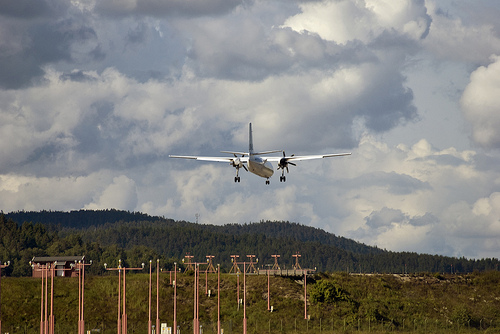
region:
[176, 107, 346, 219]
airplane landing in the mountains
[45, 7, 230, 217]
dark clouds in the background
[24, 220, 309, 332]
power lines in mountainous terrain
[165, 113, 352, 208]
airplane with landing gear down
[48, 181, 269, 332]
green mountains behind power lines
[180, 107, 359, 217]
white airplane with propellers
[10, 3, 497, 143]
dark and light clouds in the sky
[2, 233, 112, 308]
red building behind power lines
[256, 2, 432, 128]
sun hiding in clouds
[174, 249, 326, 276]
small bridge at top of hill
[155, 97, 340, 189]
a plane in the air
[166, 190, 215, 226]
A tower in the distance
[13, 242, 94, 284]
A building on a hill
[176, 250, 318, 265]
A line of red structures in the distance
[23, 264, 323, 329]
lines of lights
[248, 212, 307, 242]
A hill covered in trees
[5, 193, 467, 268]
A forest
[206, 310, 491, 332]
A fence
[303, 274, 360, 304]
A bush on a hill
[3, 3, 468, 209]
A very cloudy sky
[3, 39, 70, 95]
dark clouds rolling in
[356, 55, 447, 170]
fluffy white clouds in the sky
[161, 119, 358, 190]
white airplane in the sky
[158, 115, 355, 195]
white airplane getting ready to land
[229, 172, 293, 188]
landing gear on the airplane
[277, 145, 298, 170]
propeller on the airplane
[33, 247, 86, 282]
tiny red house on hill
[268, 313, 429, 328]
fencing along the ground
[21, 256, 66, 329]
tall pink posts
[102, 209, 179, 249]
mountains covered in green trees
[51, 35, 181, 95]
the sky is cloudy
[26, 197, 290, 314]
the hills have trees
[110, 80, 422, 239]
the plane is landing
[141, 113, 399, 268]
the plane is silver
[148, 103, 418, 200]
the plane has propellers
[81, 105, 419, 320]
plane flying above power lines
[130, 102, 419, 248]
there are three wheels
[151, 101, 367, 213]
the wheels are down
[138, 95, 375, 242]
this is a passenger jet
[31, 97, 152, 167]
the clouds are fluffy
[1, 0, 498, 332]
an outdoor daytime image of a plane landing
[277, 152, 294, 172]
the planes engine and propeller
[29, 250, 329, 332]
the approach lighting system of the airport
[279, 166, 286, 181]
the airplanes landing gear are down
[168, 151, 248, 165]
the planes wing flaps and ailerons are down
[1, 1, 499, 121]
the sky is full of grey and white clouds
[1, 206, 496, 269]
a hill is beyond the approach lights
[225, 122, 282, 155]
the airplane tail section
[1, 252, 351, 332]
the approach lighting system towers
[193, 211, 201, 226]
a communication tower above the hill